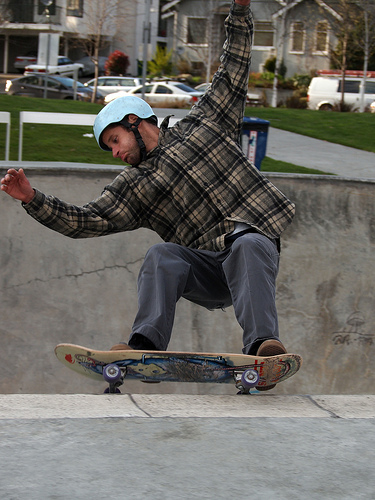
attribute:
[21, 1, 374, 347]
park — skateboard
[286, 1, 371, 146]
outside — pictured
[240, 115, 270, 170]
trash can — blue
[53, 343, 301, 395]
skateboard — pictured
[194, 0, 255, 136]
arm — aired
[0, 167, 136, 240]
arm — aired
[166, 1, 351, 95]
blue house — white-trimmed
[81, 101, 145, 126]
helmet — skateboarding, light-colored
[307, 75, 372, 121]
van — white, work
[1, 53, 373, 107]
vehicles — parked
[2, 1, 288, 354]
man — skateboarding